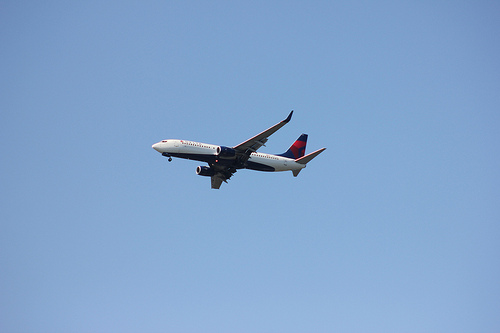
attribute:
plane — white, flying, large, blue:
[141, 103, 331, 196]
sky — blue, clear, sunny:
[5, 2, 499, 330]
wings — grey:
[193, 106, 297, 193]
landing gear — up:
[164, 150, 179, 165]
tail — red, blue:
[285, 131, 315, 160]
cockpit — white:
[147, 134, 177, 156]